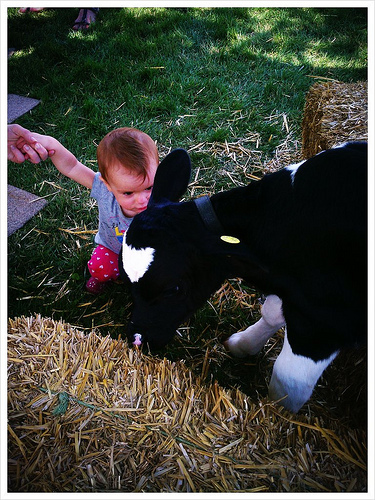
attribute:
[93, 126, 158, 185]
hair — brown, red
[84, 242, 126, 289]
pants — red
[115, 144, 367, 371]
calf — white, black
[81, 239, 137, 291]
shoes — pink, white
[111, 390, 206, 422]
hay — dry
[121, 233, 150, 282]
spots — white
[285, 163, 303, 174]
spots — white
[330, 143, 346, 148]
spots — white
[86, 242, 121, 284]
pant — pink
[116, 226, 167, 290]
spot — white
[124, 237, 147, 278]
spot — white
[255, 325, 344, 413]
front leg — white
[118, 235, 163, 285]
patch — white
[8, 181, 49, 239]
carpet — grey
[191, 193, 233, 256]
collar — black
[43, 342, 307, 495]
hay — brown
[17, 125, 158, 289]
child — squatting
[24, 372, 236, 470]
rope — green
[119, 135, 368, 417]
calf — baby, black, white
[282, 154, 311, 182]
spot — white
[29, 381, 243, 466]
string — green